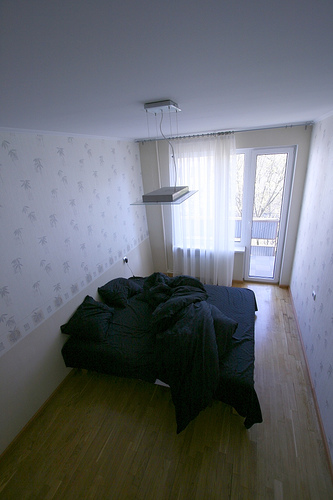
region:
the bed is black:
[80, 262, 244, 381]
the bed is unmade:
[92, 263, 294, 447]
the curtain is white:
[156, 133, 255, 295]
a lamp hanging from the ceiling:
[128, 102, 204, 221]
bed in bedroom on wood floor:
[69, 251, 265, 409]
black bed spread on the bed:
[105, 275, 243, 392]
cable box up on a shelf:
[131, 172, 202, 216]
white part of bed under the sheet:
[146, 371, 170, 390]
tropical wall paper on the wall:
[12, 179, 106, 268]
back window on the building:
[177, 155, 292, 277]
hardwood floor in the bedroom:
[68, 412, 253, 486]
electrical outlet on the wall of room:
[306, 285, 319, 301]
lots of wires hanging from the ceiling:
[133, 97, 178, 176]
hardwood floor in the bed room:
[93, 421, 189, 484]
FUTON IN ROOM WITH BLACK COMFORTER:
[55, 237, 299, 407]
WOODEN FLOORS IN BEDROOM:
[88, 268, 314, 494]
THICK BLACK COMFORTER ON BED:
[103, 250, 304, 378]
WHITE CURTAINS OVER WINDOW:
[155, 161, 245, 285]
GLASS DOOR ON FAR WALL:
[217, 152, 315, 296]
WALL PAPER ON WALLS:
[14, 139, 137, 298]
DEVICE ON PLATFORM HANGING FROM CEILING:
[155, 168, 194, 219]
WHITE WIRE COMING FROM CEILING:
[148, 118, 188, 173]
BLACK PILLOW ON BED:
[46, 297, 129, 342]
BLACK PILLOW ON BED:
[94, 268, 140, 300]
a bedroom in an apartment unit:
[2, 3, 331, 497]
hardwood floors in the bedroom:
[13, 436, 323, 496]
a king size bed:
[58, 269, 263, 435]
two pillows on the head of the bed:
[59, 275, 141, 342]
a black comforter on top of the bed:
[135, 272, 238, 434]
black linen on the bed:
[59, 272, 263, 430]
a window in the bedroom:
[169, 145, 245, 254]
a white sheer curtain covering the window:
[167, 130, 235, 272]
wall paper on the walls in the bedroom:
[2, 131, 93, 280]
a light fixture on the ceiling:
[129, 99, 198, 206]